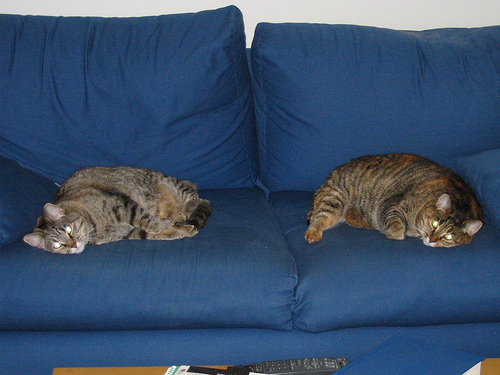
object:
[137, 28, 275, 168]
couch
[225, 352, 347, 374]
remote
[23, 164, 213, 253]
cat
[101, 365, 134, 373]
table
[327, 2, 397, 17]
wall